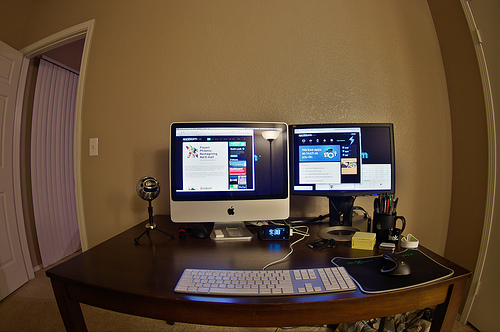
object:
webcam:
[135, 175, 162, 202]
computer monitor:
[170, 122, 287, 202]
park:
[330, 247, 454, 294]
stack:
[352, 231, 377, 250]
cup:
[372, 211, 406, 242]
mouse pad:
[322, 242, 457, 295]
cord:
[259, 220, 311, 270]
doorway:
[10, 17, 95, 273]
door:
[0, 42, 35, 303]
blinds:
[30, 54, 82, 268]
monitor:
[168, 120, 292, 224]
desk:
[46, 213, 473, 332]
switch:
[89, 137, 99, 157]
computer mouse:
[379, 252, 414, 278]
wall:
[4, 0, 456, 255]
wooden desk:
[44, 214, 477, 332]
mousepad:
[330, 247, 454, 294]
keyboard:
[172, 265, 357, 296]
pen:
[374, 192, 398, 216]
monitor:
[289, 122, 394, 197]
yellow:
[351, 231, 376, 251]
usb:
[267, 228, 281, 236]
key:
[297, 288, 304, 293]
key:
[313, 286, 322, 292]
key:
[294, 275, 302, 280]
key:
[304, 283, 313, 287]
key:
[271, 288, 281, 293]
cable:
[260, 220, 310, 271]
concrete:
[1, 0, 500, 332]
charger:
[252, 215, 312, 242]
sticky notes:
[352, 231, 377, 251]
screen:
[166, 120, 289, 223]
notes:
[351, 232, 377, 251]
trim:
[330, 245, 456, 296]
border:
[329, 247, 455, 295]